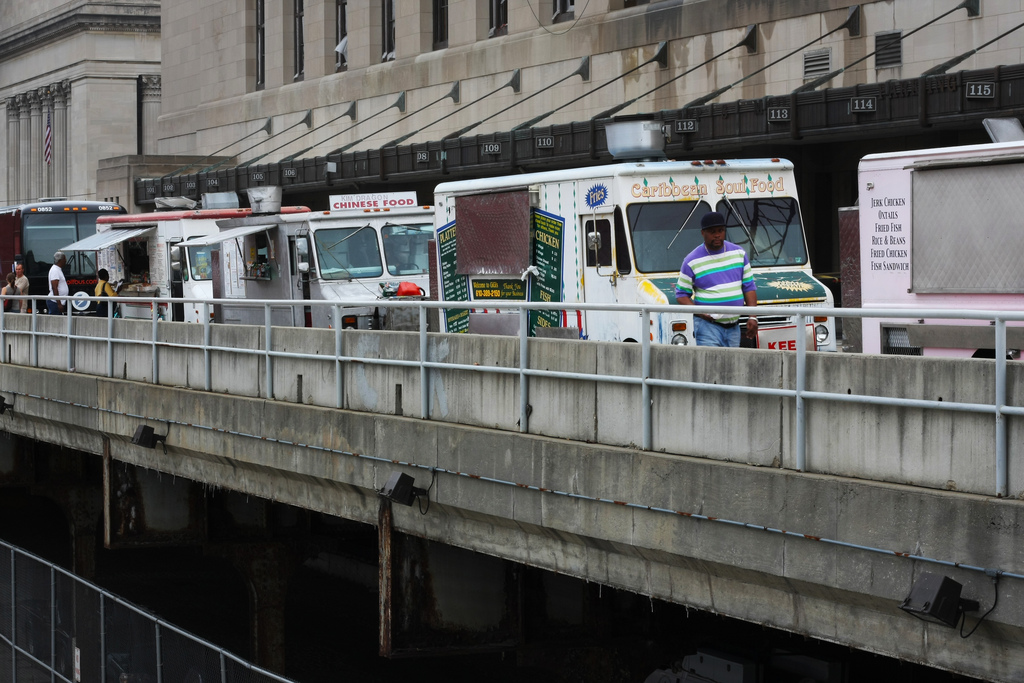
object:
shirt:
[674, 239, 761, 324]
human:
[673, 204, 765, 347]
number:
[958, 74, 997, 97]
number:
[764, 99, 792, 125]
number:
[666, 113, 713, 133]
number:
[654, 112, 703, 136]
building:
[0, 5, 1022, 201]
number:
[523, 127, 569, 151]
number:
[466, 127, 515, 154]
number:
[406, 142, 433, 169]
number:
[246, 161, 276, 181]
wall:
[817, 68, 1020, 116]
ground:
[799, 278, 892, 359]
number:
[282, 164, 298, 178]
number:
[671, 115, 698, 132]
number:
[848, 94, 876, 114]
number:
[961, 79, 997, 100]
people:
[2, 245, 140, 321]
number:
[530, 130, 561, 151]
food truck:
[205, 189, 431, 332]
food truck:
[48, 217, 160, 296]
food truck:
[424, 151, 841, 348]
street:
[5, 287, 1024, 358]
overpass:
[0, 263, 1016, 679]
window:
[454, 187, 537, 281]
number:
[674, 101, 706, 136]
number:
[410, 142, 434, 162]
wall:
[133, 6, 1020, 206]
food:
[40, 258, 150, 294]